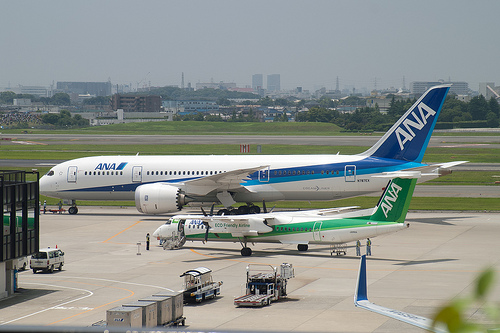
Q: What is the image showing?
A: It is showing an airport.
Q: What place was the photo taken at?
A: It was taken at the airport.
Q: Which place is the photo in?
A: It is at the airport.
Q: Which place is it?
A: It is an airport.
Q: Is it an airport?
A: Yes, it is an airport.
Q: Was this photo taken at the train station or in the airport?
A: It was taken at the airport.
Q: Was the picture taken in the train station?
A: No, the picture was taken in the airport.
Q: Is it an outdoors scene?
A: Yes, it is outdoors.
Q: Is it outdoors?
A: Yes, it is outdoors.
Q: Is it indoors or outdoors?
A: It is outdoors.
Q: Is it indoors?
A: No, it is outdoors.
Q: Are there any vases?
A: No, there are no vases.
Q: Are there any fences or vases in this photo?
A: No, there are no vases or fences.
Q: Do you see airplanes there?
A: Yes, there is an airplane.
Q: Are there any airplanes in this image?
A: Yes, there is an airplane.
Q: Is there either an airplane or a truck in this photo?
A: Yes, there is an airplane.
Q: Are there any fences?
A: No, there are no fences.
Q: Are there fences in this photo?
A: No, there are no fences.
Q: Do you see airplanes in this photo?
A: Yes, there is an airplane.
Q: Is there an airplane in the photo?
A: Yes, there is an airplane.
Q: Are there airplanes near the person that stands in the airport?
A: Yes, there is an airplane near the person.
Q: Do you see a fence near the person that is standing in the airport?
A: No, there is an airplane near the person.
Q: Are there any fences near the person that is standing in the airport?
A: No, there is an airplane near the person.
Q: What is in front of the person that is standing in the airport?
A: The plane is in front of the person.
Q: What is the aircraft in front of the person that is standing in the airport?
A: The aircraft is an airplane.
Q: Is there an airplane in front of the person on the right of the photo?
A: Yes, there is an airplane in front of the person.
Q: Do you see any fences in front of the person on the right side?
A: No, there is an airplane in front of the person.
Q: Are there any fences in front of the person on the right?
A: No, there is an airplane in front of the person.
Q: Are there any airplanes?
A: Yes, there is an airplane.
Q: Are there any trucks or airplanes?
A: Yes, there is an airplane.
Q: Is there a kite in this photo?
A: No, there are no kites.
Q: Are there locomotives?
A: No, there are no locomotives.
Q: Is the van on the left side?
A: Yes, the van is on the left of the image.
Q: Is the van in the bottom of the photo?
A: Yes, the van is in the bottom of the image.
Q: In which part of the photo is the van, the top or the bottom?
A: The van is in the bottom of the image.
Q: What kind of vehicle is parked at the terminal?
A: The vehicle is a van.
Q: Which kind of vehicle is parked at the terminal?
A: The vehicle is a van.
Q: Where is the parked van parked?
A: The van is parked at the terminal.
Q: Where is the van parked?
A: The van is parked at the terminal.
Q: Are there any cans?
A: No, there are no cans.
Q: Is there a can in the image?
A: No, there are no cans.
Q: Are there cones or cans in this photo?
A: No, there are no cans or cones.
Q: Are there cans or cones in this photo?
A: No, there are no cans or cones.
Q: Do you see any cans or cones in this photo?
A: No, there are no cans or cones.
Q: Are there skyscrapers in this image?
A: Yes, there is a skyscraper.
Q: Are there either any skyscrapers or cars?
A: Yes, there is a skyscraper.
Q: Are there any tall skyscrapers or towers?
A: Yes, there is a tall skyscraper.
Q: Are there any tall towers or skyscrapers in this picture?
A: Yes, there is a tall skyscraper.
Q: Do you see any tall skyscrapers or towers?
A: Yes, there is a tall skyscraper.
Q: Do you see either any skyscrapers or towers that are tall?
A: Yes, the skyscraper is tall.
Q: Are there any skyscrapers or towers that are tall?
A: Yes, the skyscraper is tall.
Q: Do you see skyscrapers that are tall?
A: Yes, there is a tall skyscraper.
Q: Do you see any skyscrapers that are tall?
A: Yes, there is a skyscraper that is tall.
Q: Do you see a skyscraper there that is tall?
A: Yes, there is a skyscraper that is tall.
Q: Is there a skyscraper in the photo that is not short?
A: Yes, there is a tall skyscraper.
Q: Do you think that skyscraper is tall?
A: Yes, the skyscraper is tall.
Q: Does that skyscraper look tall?
A: Yes, the skyscraper is tall.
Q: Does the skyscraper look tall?
A: Yes, the skyscraper is tall.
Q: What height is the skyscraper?
A: The skyscraper is tall.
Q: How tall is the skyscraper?
A: The skyscraper is tall.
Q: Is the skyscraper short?
A: No, the skyscraper is tall.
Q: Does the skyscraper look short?
A: No, the skyscraper is tall.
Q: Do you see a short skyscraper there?
A: No, there is a skyscraper but it is tall.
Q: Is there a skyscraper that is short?
A: No, there is a skyscraper but it is tall.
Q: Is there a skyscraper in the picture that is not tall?
A: No, there is a skyscraper but it is tall.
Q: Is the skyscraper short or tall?
A: The skyscraper is tall.